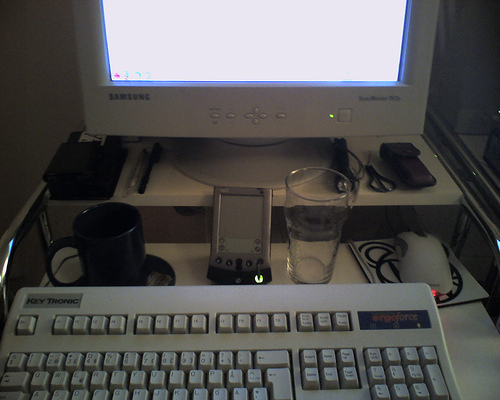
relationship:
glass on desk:
[281, 160, 351, 282] [4, 237, 499, 397]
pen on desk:
[135, 142, 163, 195] [44, 124, 499, 215]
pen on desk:
[327, 134, 358, 194] [44, 124, 499, 215]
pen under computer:
[135, 142, 163, 195] [71, 0, 440, 139]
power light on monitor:
[324, 109, 336, 121] [65, 2, 445, 193]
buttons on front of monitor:
[199, 107, 365, 157] [55, 11, 446, 161]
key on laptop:
[189, 312, 211, 334] [1, 280, 464, 398]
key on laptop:
[172, 309, 186, 337] [1, 280, 464, 398]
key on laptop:
[52, 314, 75, 334] [1, 280, 464, 398]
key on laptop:
[135, 315, 154, 334] [1, 280, 464, 398]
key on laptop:
[216, 312, 235, 333] [1, 280, 464, 398]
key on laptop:
[297, 312, 315, 332] [1, 280, 464, 398]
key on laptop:
[299, 349, 318, 371] [1, 280, 464, 398]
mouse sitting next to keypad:
[393, 212, 460, 292] [1, 280, 463, 399]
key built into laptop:
[272, 311, 289, 333] [2, 1, 465, 398]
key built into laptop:
[297, 312, 312, 328] [2, 1, 465, 398]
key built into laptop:
[136, 312, 151, 333] [2, 1, 465, 398]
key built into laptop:
[301, 369, 318, 386] [2, 1, 465, 398]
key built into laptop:
[186, 370, 201, 385] [2, 1, 465, 398]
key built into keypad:
[314, 306, 336, 332] [1, 280, 463, 399]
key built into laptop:
[331, 312, 351, 330] [2, 1, 465, 398]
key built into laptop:
[297, 349, 317, 367] [2, 1, 465, 398]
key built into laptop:
[337, 348, 356, 365] [2, 1, 465, 398]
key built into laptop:
[212, 315, 237, 332] [2, 1, 465, 398]